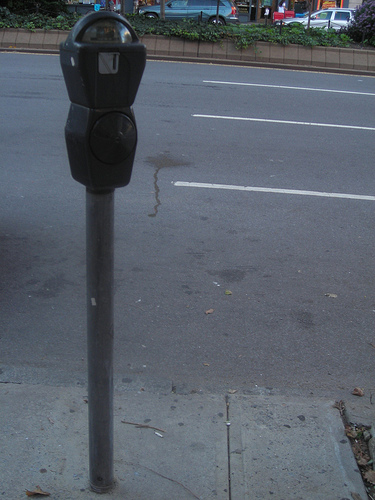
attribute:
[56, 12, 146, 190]
parking meter — dull, for parking, hour glass shaped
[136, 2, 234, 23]
van — green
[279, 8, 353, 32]
suv — here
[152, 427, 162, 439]
cigarette — here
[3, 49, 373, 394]
road — here, blacktopped, paved, clear, dirty, cracky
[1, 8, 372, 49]
bushes — green color, here, green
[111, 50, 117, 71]
coin slot — here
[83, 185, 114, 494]
post — here, metallic, straight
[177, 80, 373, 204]
stripes — white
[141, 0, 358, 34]
cars — here, parked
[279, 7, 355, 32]
car — parked, grey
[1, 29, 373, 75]
wall — here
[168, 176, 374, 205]
line — white, here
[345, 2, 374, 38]
bush — floral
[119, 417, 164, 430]
stick — dr